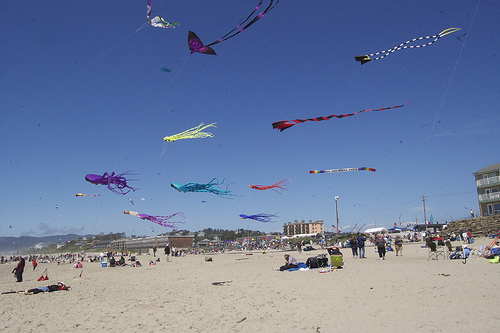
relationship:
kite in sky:
[143, 3, 179, 30] [6, 5, 120, 120]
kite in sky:
[188, 31, 217, 57] [6, 5, 120, 120]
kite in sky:
[354, 52, 372, 66] [6, 5, 120, 120]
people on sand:
[341, 232, 418, 261] [1, 251, 500, 333]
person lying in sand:
[22, 282, 68, 296] [1, 251, 500, 333]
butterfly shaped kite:
[187, 0, 280, 57] [188, 31, 217, 57]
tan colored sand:
[257, 272, 298, 302] [1, 251, 500, 333]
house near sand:
[472, 160, 500, 218] [1, 251, 500, 333]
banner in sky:
[308, 164, 377, 175] [6, 5, 120, 120]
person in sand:
[22, 282, 68, 296] [1, 251, 500, 333]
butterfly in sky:
[187, 0, 280, 57] [6, 5, 120, 120]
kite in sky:
[170, 178, 245, 203] [6, 5, 120, 120]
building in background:
[283, 217, 324, 237] [64, 212, 479, 252]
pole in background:
[334, 194, 342, 234] [64, 212, 479, 252]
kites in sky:
[77, 173, 292, 229] [6, 5, 120, 120]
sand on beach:
[1, 251, 500, 333] [2, 240, 499, 332]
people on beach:
[341, 232, 418, 261] [2, 240, 499, 332]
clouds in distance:
[20, 219, 86, 237] [2, 224, 142, 251]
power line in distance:
[424, 194, 479, 202] [2, 224, 142, 251]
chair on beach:
[427, 238, 447, 262] [2, 240, 499, 332]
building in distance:
[283, 217, 324, 237] [2, 224, 142, 251]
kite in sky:
[163, 122, 219, 143] [6, 5, 120, 120]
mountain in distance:
[3, 234, 83, 251] [2, 224, 142, 251]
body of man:
[276, 254, 299, 271] [275, 254, 302, 271]